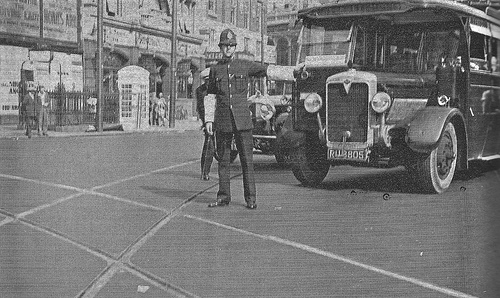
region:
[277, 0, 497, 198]
part of an old truck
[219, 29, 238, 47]
a man's hat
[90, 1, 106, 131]
part of a tall street pole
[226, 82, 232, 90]
a coat button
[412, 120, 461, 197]
a wheel of a truck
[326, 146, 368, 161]
a license plate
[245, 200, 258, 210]
part of a man's shoe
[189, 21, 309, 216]
a man standing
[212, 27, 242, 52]
a hat on head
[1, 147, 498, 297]
lines on the street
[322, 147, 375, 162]
tag on front of car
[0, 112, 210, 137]
the sidewalk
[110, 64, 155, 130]
ENTRANCE TO BUILDING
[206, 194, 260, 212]
the dress shoes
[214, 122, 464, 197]
the front wheels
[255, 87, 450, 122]
lights on the front of car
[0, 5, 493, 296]
the whole town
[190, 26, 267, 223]
a man in uniform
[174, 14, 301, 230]
a man in uniform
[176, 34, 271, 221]
a man in uniform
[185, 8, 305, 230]
a man in uniform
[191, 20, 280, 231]
a man in uniform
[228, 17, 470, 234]
bus in the street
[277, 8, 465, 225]
bus in the street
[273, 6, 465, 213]
bus in the street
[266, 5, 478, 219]
bus in the street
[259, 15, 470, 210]
bus in the street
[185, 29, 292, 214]
police officer directing traffic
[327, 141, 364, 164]
license plate with white lettering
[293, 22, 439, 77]
windows on front of the bus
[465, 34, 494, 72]
windows on side of the bus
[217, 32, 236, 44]
helmet officer is wearing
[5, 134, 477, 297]
street the officer is standing on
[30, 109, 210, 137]
sidewalk along the road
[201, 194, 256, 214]
black shoes the officer is wearing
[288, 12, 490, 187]
bus stopped on the road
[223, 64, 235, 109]
buttons on officer's uniform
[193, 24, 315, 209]
policeman directing traffic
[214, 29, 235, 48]
helmet of the policeman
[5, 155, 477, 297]
lines on the road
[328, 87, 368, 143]
front grill of the bus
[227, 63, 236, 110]
buttons on the uniform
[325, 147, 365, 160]
license plate on the bus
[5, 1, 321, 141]
buildings behind the policeman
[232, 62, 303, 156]
car behind the policeman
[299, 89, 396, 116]
lights on the bus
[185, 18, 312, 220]
this is an officer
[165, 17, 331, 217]
office is wearing a uniform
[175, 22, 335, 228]
officer standing in street